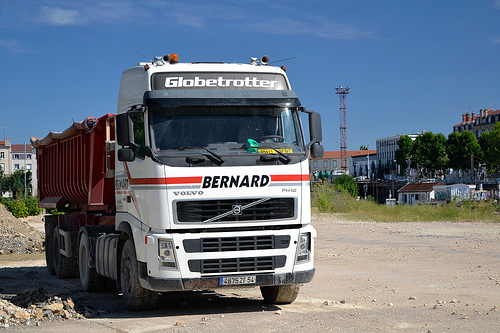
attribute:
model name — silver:
[173, 190, 203, 196]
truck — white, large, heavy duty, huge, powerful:
[30, 37, 317, 307]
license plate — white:
[219, 276, 256, 285]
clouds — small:
[45, 0, 381, 40]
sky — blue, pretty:
[1, 0, 498, 150]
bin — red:
[30, 114, 114, 208]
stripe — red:
[125, 176, 313, 184]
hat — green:
[245, 138, 259, 155]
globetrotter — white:
[165, 76, 277, 87]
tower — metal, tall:
[337, 86, 349, 182]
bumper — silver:
[150, 269, 317, 292]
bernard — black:
[201, 176, 269, 187]